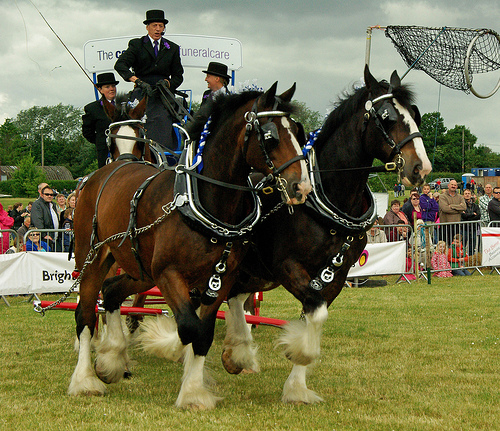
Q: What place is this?
A: It is a field.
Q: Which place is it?
A: It is a field.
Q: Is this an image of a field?
A: Yes, it is showing a field.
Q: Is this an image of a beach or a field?
A: It is showing a field.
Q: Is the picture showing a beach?
A: No, the picture is showing a field.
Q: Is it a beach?
A: No, it is a field.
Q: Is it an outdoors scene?
A: Yes, it is outdoors.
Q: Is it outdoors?
A: Yes, it is outdoors.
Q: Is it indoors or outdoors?
A: It is outdoors.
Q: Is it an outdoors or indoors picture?
A: It is outdoors.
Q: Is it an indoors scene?
A: No, it is outdoors.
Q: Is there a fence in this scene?
A: Yes, there is a fence.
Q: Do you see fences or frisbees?
A: Yes, there is a fence.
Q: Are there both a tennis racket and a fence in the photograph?
A: No, there is a fence but no rackets.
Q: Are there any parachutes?
A: No, there are no parachutes.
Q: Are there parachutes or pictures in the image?
A: No, there are no parachutes or pictures.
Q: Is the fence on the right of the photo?
A: Yes, the fence is on the right of the image.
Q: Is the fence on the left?
A: No, the fence is on the right of the image.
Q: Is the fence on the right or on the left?
A: The fence is on the right of the image.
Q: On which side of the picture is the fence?
A: The fence is on the right of the image.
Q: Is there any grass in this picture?
A: Yes, there is grass.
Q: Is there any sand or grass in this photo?
A: Yes, there is grass.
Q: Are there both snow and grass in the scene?
A: No, there is grass but no snow.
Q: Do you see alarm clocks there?
A: No, there are no alarm clocks.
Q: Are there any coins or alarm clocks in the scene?
A: No, there are no alarm clocks or coins.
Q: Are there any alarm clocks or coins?
A: No, there are no alarm clocks or coins.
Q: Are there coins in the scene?
A: No, there are no coins.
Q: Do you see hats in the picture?
A: Yes, there is a hat.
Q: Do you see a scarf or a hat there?
A: Yes, there is a hat.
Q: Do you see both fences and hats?
A: Yes, there are both a hat and a fence.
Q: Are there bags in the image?
A: No, there are no bags.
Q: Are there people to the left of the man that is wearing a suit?
A: Yes, there is a person to the left of the man.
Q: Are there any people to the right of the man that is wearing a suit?
A: No, the person is to the left of the man.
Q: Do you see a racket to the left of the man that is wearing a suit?
A: No, there is a person to the left of the man.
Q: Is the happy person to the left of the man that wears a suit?
A: Yes, the person is to the left of the man.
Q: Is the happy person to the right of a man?
A: No, the person is to the left of a man.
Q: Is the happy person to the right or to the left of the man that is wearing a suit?
A: The person is to the left of the man.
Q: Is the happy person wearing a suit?
A: Yes, the person is wearing a suit.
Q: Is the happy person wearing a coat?
A: No, the person is wearing a suit.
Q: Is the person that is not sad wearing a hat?
A: Yes, the person is wearing a hat.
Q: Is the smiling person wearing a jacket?
A: No, the person is wearing a hat.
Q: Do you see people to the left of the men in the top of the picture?
A: Yes, there is a person to the left of the men.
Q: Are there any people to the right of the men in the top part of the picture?
A: No, the person is to the left of the men.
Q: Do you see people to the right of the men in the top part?
A: No, the person is to the left of the men.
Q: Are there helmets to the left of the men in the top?
A: No, there is a person to the left of the men.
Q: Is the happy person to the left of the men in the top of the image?
A: Yes, the person is to the left of the men.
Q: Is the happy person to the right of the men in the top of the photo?
A: No, the person is to the left of the men.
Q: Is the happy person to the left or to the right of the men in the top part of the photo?
A: The person is to the left of the men.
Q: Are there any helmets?
A: No, there are no helmets.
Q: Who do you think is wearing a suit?
A: The man is wearing a suit.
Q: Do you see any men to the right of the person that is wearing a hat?
A: Yes, there is a man to the right of the person.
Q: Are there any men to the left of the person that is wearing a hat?
A: No, the man is to the right of the person.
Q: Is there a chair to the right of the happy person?
A: No, there is a man to the right of the person.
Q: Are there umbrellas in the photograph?
A: No, there are no umbrellas.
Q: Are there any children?
A: Yes, there are children.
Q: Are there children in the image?
A: Yes, there are children.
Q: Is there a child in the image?
A: Yes, there are children.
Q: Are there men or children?
A: Yes, there are children.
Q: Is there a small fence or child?
A: Yes, there are small children.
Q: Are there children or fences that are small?
A: Yes, the children are small.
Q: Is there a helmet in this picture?
A: No, there are no helmets.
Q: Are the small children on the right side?
A: Yes, the kids are on the right of the image.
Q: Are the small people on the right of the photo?
A: Yes, the kids are on the right of the image.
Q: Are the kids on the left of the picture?
A: No, the kids are on the right of the image.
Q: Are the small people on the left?
A: No, the kids are on the right of the image.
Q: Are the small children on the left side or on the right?
A: The kids are on the right of the image.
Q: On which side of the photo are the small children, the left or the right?
A: The kids are on the right of the image.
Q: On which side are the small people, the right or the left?
A: The kids are on the right of the image.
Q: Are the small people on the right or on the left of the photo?
A: The kids are on the right of the image.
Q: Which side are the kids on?
A: The kids are on the right of the image.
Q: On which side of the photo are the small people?
A: The kids are on the right of the image.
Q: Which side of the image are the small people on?
A: The kids are on the right of the image.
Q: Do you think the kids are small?
A: Yes, the kids are small.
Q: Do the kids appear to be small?
A: Yes, the kids are small.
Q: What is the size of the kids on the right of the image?
A: The children are small.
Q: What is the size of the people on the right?
A: The children are small.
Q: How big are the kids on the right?
A: The children are small.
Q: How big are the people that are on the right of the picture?
A: The children are small.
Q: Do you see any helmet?
A: No, there are no helmets.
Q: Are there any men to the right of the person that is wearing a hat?
A: Yes, there are men to the right of the person.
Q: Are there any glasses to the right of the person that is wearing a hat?
A: No, there are men to the right of the person.